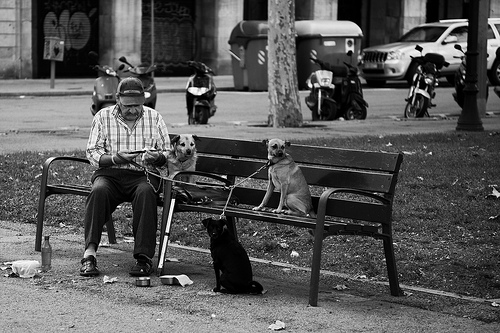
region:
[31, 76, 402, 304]
man sitting in one section of a bench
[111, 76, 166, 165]
man looking down at object he is holding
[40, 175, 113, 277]
bottle on ground next to man's leg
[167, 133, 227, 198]
dog sitting behind arm rest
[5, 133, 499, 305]
grassy area with scattered leaves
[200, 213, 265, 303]
dark dog on ground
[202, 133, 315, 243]
dogs connected to each other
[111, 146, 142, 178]
man has leash loop on his hand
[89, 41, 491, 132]
motorcycles parked near each other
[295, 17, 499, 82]
vehicle near large block-like object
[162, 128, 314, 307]
A group of three dogs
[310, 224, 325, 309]
The leg of a park bench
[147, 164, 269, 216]
The chains connecting the dog together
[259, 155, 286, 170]
The collor of the dog being pulled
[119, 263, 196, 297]
Dishes on the ground for the animals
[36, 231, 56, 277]
A plastic bottle standing up in the dirt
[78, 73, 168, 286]
The man sitting on the bench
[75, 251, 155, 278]
A pair of black mens sandals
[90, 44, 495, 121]
A row of bikes parked along the side of the road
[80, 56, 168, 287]
A man looking down to read something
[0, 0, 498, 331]
the scene is at a roadside on the street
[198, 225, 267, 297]
a black sitted dog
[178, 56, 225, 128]
scooters packed on the roadside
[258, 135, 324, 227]
a brown dog seated on the chair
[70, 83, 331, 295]
an old man seated with tree dogs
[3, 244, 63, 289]
litters on the street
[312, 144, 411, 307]
a wooden black seat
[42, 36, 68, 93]
a post office post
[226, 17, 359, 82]
a large litter bin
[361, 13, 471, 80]
a whhite car parked across the street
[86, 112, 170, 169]
A checkered shirt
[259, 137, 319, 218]
A dog in the photo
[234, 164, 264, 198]
A brace on the dog neck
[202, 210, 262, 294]
A black dog in the photo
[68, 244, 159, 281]
Black shoes in the photo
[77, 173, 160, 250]
Black pants in the photo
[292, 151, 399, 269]
A bench in the photo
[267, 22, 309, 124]
A tree trunk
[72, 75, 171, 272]
A man seated on the bench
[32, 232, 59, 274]
A bottle on the floor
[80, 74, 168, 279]
a man sitting on a bench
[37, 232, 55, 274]
a bottle on the ground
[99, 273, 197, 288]
garbage left on the ground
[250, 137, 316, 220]
a dog sitting on a bench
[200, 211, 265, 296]
a black dog sitting on the ground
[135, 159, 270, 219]
a rope the man is using as a leash for two dogs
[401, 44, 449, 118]
a motorcycle parked on the street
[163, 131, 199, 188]
a dog sitting on the bench next to the man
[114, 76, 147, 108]
a dark colored baseball cap on the man's head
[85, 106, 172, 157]
a plaid shirt the man is wearing